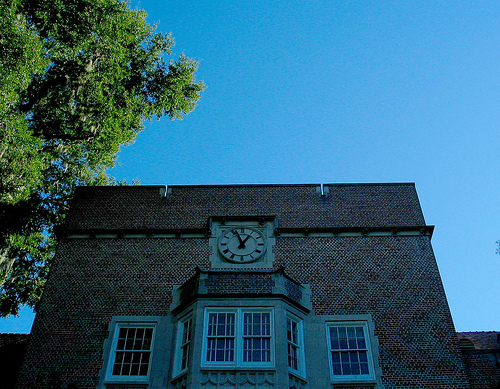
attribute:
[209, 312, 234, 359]
rods — iron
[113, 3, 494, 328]
blue sky — clear blue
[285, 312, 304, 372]
window — on the building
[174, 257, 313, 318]
stone balcony — on the building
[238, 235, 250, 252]
hand — is on clock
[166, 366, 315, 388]
design — under windows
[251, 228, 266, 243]
numeral — are roman numerals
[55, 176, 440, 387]
building — on the building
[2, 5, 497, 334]
sky — on the building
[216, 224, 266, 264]
clock — round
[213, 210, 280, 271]
clock — is on old building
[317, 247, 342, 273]
stone — on the building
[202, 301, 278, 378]
window — are bay windows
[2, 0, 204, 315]
tree top — on the building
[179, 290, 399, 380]
windows — on the building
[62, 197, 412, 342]
windows — are double hung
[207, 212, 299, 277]
clock — on the building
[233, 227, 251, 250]
hands — black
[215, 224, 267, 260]
clock — is on old building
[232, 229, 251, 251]
clock hands — are metal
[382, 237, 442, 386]
stone work — on the building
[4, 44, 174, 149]
tree — on the building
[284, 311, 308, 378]
windows — on the building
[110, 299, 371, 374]
windows — on the building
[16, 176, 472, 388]
building — on the building,  has wood guttering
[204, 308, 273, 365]
window — big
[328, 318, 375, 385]
window — has  a white pane, has a white pane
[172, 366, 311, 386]
ledge — decorative